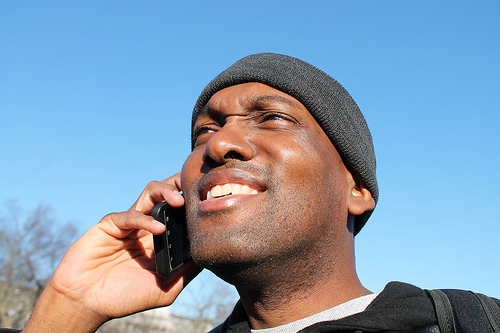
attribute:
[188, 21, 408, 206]
bonnet — in the picture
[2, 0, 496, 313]
sky — Clear, blue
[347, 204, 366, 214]
tip — in the picture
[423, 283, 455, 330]
strap — black, thin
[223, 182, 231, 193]
tooth — in the picture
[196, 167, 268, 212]
lips — smiling